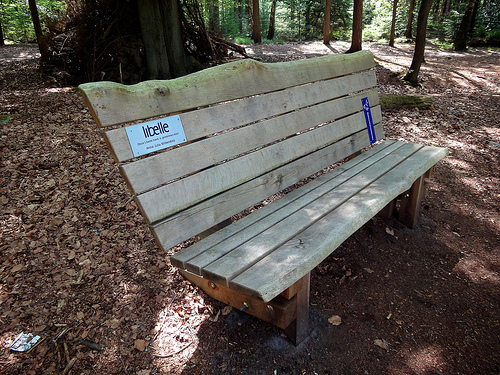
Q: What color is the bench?
A: Brown.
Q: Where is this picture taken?
A: A forest.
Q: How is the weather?
A: Sunny.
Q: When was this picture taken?
A: Daytime.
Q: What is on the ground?
A: Leaves.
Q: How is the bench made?
A: Of wood.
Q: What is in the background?
A: Trees.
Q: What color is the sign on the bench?
A: Blue.